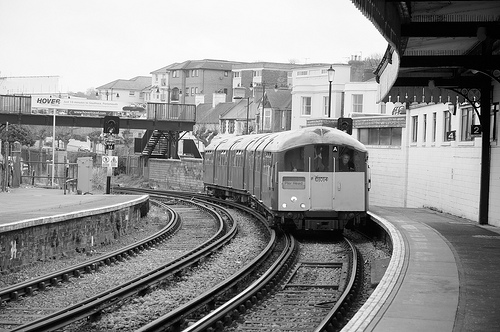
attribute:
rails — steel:
[214, 282, 227, 290]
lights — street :
[126, 64, 349, 147]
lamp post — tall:
[321, 61, 341, 123]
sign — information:
[423, 107, 473, 154]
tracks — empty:
[59, 162, 239, 328]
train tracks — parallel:
[109, 225, 360, 326]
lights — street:
[237, 53, 379, 128]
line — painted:
[338, 210, 405, 330]